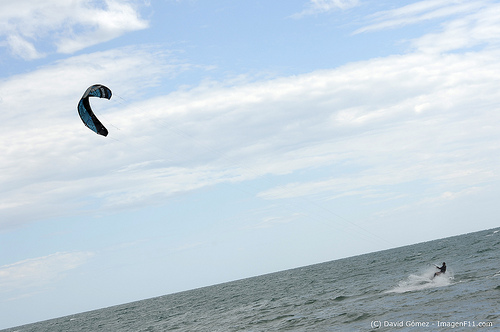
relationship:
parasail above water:
[73, 79, 120, 145] [0, 226, 499, 331]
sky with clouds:
[3, 2, 499, 227] [229, 74, 447, 194]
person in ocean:
[431, 260, 449, 280] [0, 226, 499, 331]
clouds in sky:
[229, 74, 447, 194] [3, 2, 499, 227]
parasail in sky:
[73, 79, 120, 145] [3, 2, 499, 227]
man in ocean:
[431, 260, 449, 280] [0, 226, 499, 331]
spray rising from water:
[401, 274, 456, 285] [0, 226, 499, 331]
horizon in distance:
[17, 227, 488, 326] [231, 271, 236, 273]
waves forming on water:
[254, 294, 366, 310] [0, 226, 499, 331]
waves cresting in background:
[254, 294, 366, 310] [42, 252, 499, 267]